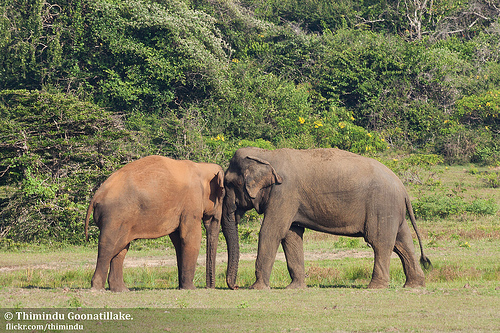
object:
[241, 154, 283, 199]
ear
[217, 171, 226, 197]
ear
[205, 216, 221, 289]
trunk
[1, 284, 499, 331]
grass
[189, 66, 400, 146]
bush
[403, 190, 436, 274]
tail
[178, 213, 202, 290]
legs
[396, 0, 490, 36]
trees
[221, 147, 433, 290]
elephant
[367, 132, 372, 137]
flowers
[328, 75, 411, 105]
ground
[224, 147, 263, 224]
heads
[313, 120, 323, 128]
flower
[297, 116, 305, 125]
flower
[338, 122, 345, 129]
flower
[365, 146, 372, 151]
flower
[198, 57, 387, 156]
tree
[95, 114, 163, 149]
stick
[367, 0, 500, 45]
banches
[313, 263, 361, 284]
grass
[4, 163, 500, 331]
field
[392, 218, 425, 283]
leg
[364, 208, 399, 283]
leg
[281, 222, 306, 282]
leg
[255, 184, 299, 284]
leg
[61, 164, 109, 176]
stick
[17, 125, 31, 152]
stick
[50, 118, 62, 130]
stick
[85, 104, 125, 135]
stick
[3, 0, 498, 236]
mountain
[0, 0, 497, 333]
wild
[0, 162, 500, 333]
ground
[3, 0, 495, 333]
background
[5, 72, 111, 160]
bushes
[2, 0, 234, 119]
tree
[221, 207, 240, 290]
trunk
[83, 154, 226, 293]
elephant